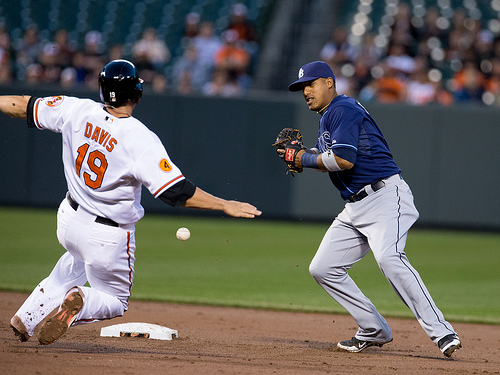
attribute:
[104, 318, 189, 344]
base — white, baseball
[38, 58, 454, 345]
men — playing baseball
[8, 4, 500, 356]
game — professional, baseball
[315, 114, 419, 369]
uniform — blue, gray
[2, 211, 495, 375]
ground — brown, muddy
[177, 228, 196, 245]
baseball — flying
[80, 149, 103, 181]
numbers — orange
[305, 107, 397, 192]
shirt — blue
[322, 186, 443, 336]
pants — white, gray, part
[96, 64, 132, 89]
helmet — black, blue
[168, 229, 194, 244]
ball — white, in air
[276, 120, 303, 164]
glove — black, leather, baseball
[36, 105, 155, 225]
shirt — white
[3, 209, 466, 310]
grass — green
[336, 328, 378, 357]
cleat — baseball, nike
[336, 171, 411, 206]
belt — black